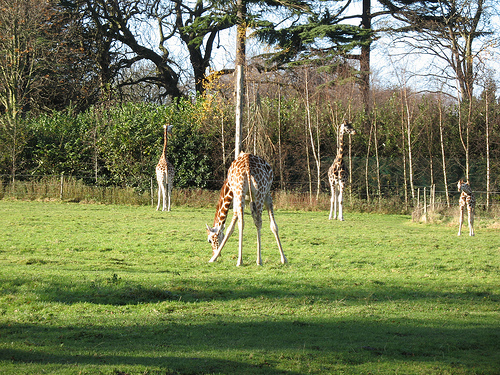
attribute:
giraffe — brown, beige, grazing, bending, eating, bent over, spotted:
[196, 139, 289, 278]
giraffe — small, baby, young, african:
[445, 179, 481, 248]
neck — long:
[217, 185, 234, 231]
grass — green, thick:
[65, 240, 494, 352]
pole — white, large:
[230, 65, 249, 154]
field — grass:
[19, 175, 475, 374]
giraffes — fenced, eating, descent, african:
[139, 118, 479, 257]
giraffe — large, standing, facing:
[309, 108, 360, 220]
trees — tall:
[119, 18, 458, 141]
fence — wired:
[42, 165, 417, 225]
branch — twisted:
[400, 38, 447, 85]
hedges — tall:
[166, 4, 224, 103]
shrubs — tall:
[367, 103, 489, 189]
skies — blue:
[204, 27, 475, 66]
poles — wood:
[19, 173, 122, 198]